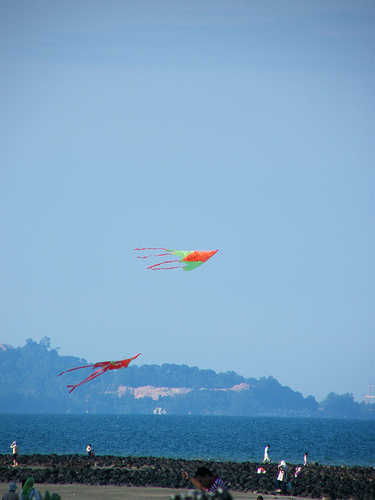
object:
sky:
[33, 102, 339, 406]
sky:
[31, 68, 321, 386]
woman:
[7, 476, 18, 496]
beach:
[52, 455, 304, 496]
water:
[9, 398, 369, 466]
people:
[8, 443, 24, 469]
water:
[62, 407, 362, 447]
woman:
[21, 476, 36, 498]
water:
[33, 400, 354, 482]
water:
[7, 413, 304, 478]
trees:
[258, 379, 268, 393]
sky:
[7, 337, 266, 420]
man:
[176, 462, 230, 498]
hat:
[6, 481, 17, 491]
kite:
[131, 244, 220, 271]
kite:
[53, 351, 145, 390]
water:
[128, 415, 239, 447]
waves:
[148, 421, 206, 450]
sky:
[258, 125, 343, 316]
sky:
[206, 282, 268, 335]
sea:
[200, 413, 230, 430]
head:
[193, 464, 213, 484]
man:
[11, 438, 21, 461]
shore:
[7, 460, 62, 470]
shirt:
[204, 474, 229, 492]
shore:
[244, 456, 288, 468]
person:
[261, 442, 273, 465]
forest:
[174, 368, 191, 380]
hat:
[23, 476, 37, 486]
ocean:
[171, 410, 331, 444]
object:
[286, 479, 305, 489]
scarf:
[270, 452, 291, 469]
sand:
[67, 474, 160, 489]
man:
[263, 442, 274, 464]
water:
[136, 418, 325, 453]